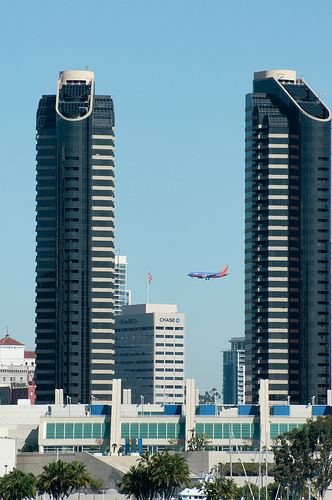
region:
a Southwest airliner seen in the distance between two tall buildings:
[11, 65, 330, 423]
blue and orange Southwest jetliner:
[181, 260, 236, 291]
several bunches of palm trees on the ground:
[8, 440, 191, 498]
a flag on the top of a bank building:
[142, 266, 158, 303]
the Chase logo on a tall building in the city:
[156, 312, 180, 324]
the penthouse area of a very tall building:
[29, 67, 118, 113]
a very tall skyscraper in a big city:
[229, 60, 330, 402]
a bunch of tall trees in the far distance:
[201, 386, 223, 403]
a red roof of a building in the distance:
[2, 332, 23, 346]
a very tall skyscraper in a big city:
[20, 66, 125, 399]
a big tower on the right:
[232, 58, 330, 399]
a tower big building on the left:
[20, 57, 126, 395]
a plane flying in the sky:
[181, 251, 237, 290]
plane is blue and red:
[183, 258, 237, 287]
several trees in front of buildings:
[0, 413, 331, 498]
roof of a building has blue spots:
[32, 395, 330, 424]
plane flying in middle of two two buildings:
[0, 240, 331, 295]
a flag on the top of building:
[138, 261, 158, 302]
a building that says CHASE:
[114, 295, 192, 400]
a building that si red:
[4, 381, 39, 406]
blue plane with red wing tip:
[189, 264, 233, 280]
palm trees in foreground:
[0, 459, 284, 497]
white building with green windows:
[41, 412, 314, 453]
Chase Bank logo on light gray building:
[120, 304, 185, 407]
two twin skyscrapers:
[31, 62, 330, 398]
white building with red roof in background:
[0, 330, 37, 366]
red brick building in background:
[10, 377, 35, 401]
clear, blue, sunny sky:
[0, 5, 329, 404]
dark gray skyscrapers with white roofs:
[32, 64, 331, 401]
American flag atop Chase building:
[144, 269, 153, 299]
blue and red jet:
[183, 262, 231, 280]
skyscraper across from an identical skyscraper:
[26, 64, 120, 417]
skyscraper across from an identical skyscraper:
[228, 66, 326, 421]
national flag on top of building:
[143, 264, 160, 305]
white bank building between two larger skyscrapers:
[113, 300, 186, 421]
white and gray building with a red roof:
[0, 323, 38, 385]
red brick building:
[0, 380, 44, 409]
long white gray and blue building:
[31, 370, 330, 499]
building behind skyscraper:
[220, 332, 257, 406]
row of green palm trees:
[1, 446, 249, 499]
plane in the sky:
[179, 256, 234, 292]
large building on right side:
[227, 56, 329, 405]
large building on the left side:
[23, 55, 124, 396]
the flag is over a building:
[141, 265, 156, 302]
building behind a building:
[217, 332, 250, 409]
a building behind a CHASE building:
[112, 248, 140, 304]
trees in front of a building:
[106, 444, 196, 496]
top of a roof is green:
[45, 416, 305, 447]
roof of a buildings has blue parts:
[45, 394, 330, 415]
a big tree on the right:
[262, 409, 330, 498]